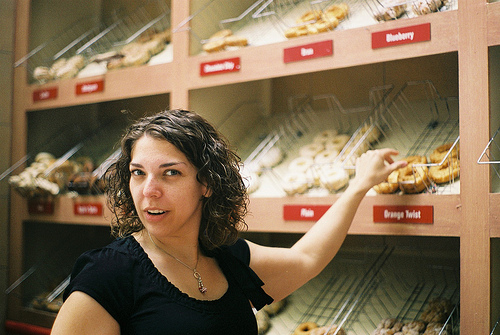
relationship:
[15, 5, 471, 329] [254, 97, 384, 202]
shelves with wire bin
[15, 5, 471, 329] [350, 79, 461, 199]
shelves with wire bin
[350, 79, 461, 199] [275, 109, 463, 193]
wire bin full of different types of bagels